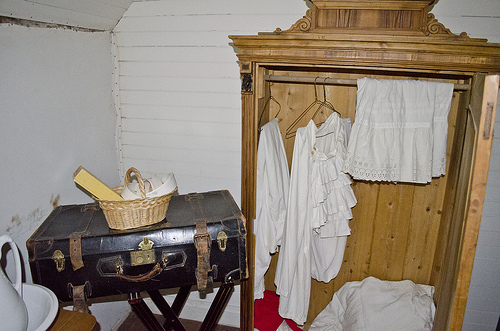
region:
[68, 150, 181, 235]
Small wicker basket holding items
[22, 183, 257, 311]
Weathered black and brown suitcase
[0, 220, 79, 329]
Wash basin and pitcher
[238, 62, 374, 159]
Metal coat hangers holding white linens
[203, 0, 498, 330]
Ornate wooden wardrobe with various items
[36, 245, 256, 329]
Suitcase stand supporting suitcase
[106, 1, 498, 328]
Painted white brick wall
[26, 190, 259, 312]
Black suitcase with brown leather straps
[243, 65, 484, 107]
Wooden pole to hang clothes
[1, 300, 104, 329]
Table supporting a wash basin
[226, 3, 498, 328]
Pale brown wood cabinet with open door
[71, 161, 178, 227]
Wicker basket filled with white and tan items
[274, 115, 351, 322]
White shirt with frills on front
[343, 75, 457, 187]
White clothes item with lace trim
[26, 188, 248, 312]
Battered black case with brown straps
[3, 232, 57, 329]
White vase in white bowl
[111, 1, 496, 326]
Brown cabinet against white wood wall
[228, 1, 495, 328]
Cabinet filled with white and red clothes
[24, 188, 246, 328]
Black suitcase resting on a stand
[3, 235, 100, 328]
White bowl and basin on wood table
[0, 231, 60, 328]
water pitcher and bowl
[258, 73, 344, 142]
four wire hangers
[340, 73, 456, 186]
white slip with ribbons and eyelet material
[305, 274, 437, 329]
blanket partially folded in bottom of wardrobe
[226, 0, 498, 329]
carved wooden clothes cupboard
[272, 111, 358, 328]
frilly front white blouse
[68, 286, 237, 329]
black luggage stand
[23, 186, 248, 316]
worn leather and brass suitcase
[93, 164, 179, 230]
light brown woven basket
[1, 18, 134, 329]
fabric tacked to side wall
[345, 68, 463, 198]
white cloth hanging in closet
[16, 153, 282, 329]
black suitcase on stand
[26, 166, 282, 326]
wicker basket on suitcase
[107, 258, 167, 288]
brown handle on suitcase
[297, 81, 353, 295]
clothing on clothes hanger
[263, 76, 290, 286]
clothing on clothes hanger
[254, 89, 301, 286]
white clothing on clothes hanger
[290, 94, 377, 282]
white clothing on clothes hanger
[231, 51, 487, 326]
large light color wooden closet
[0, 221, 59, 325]
white water pitcher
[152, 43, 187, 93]
white board on wall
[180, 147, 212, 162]
white board on wall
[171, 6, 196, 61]
white board on wall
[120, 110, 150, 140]
white board on wall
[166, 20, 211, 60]
white board on wall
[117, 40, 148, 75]
white board on wall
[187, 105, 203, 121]
white board on wall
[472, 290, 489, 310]
white board on wall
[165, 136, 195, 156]
white board on wall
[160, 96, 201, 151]
white board on wall